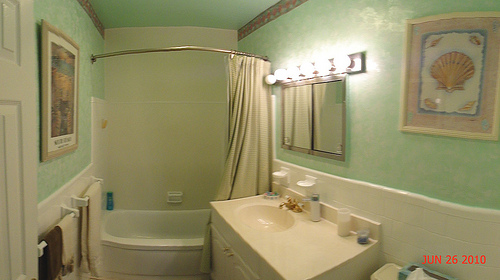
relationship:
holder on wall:
[166, 191, 183, 203] [127, 132, 218, 207]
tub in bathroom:
[92, 198, 217, 272] [2, 0, 499, 277]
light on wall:
[331, 53, 351, 74] [234, 2, 496, 211]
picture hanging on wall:
[399, 8, 498, 142] [234, 2, 496, 211]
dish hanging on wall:
[163, 186, 185, 201] [102, 26, 242, 211]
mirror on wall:
[282, 75, 344, 157] [237, 0, 499, 279]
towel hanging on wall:
[81, 181, 117, 280] [34, 4, 101, 278]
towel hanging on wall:
[54, 214, 79, 280] [34, 4, 101, 278]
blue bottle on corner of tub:
[102, 186, 117, 212] [95, 200, 218, 278]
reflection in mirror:
[278, 80, 347, 158] [271, 79, 355, 166]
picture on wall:
[399, 8, 498, 142] [239, 4, 484, 221]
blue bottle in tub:
[107, 191, 114, 210] [99, 202, 211, 266]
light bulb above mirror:
[261, 72, 274, 88] [268, 75, 360, 166]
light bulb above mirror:
[271, 65, 290, 82] [268, 75, 360, 166]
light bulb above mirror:
[279, 61, 302, 83] [268, 75, 360, 166]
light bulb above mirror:
[296, 58, 316, 79] [268, 75, 360, 166]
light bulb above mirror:
[313, 56, 333, 76] [268, 75, 360, 166]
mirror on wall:
[281, 75, 347, 161] [234, 2, 484, 196]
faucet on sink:
[276, 193, 296, 212] [206, 180, 384, 271]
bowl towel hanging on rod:
[41, 226, 63, 280] [38, 204, 75, 246]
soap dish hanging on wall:
[297, 174, 320, 189] [264, 92, 496, 276]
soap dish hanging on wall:
[267, 165, 288, 187] [264, 92, 496, 276]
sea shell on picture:
[425, 48, 477, 90] [398, 11, 498, 142]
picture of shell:
[399, 8, 498, 142] [429, 49, 478, 95]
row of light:
[262, 54, 367, 87] [265, 73, 277, 86]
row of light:
[262, 54, 367, 87] [273, 66, 291, 82]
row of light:
[262, 54, 367, 87] [286, 63, 302, 82]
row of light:
[262, 54, 367, 87] [298, 59, 317, 79]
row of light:
[262, 54, 367, 87] [316, 57, 333, 77]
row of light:
[262, 54, 367, 87] [332, 52, 354, 75]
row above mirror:
[262, 54, 367, 87] [276, 76, 354, 158]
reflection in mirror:
[278, 86, 337, 156] [285, 89, 338, 151]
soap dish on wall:
[163, 187, 186, 208] [102, 26, 242, 211]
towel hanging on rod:
[81, 181, 117, 280] [69, 175, 103, 207]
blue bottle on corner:
[107, 191, 114, 210] [103, 102, 116, 216]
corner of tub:
[103, 102, 116, 216] [94, 208, 211, 278]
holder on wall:
[167, 191, 184, 203] [109, 103, 228, 208]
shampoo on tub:
[104, 190, 116, 210] [94, 208, 211, 278]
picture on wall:
[34, 19, 82, 164] [31, 4, 107, 204]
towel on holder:
[81, 181, 117, 280] [70, 173, 106, 212]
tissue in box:
[403, 267, 435, 279] [400, 255, 451, 278]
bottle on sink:
[306, 189, 326, 223] [234, 198, 296, 239]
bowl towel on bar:
[41, 225, 64, 278] [38, 207, 81, 258]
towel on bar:
[78, 165, 118, 276] [68, 171, 108, 207]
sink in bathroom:
[238, 203, 295, 233] [2, 0, 499, 277]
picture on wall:
[398, 11, 498, 142] [351, 122, 498, 203]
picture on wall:
[35, 15, 83, 163] [31, 4, 107, 204]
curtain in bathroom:
[196, 51, 274, 279] [158, 65, 240, 135]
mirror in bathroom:
[281, 75, 347, 161] [2, 0, 499, 277]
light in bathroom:
[331, 53, 351, 74] [2, 0, 499, 277]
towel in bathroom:
[81, 181, 117, 280] [2, 0, 499, 277]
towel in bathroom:
[53, 208, 80, 279] [2, 0, 499, 277]